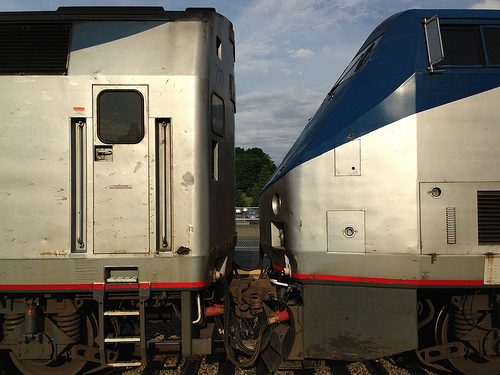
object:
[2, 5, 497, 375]
train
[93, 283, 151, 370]
steps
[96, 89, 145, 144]
window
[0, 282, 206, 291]
line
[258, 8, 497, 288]
cabin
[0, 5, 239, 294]
cabin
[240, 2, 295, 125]
sky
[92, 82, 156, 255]
door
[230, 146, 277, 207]
tree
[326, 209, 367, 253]
panel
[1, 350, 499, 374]
tracks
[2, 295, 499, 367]
under-carriage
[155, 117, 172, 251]
handgrip